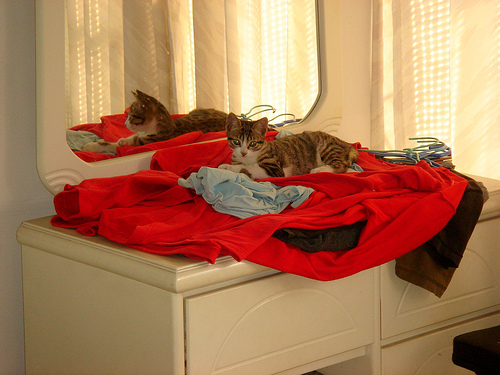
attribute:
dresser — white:
[14, 173, 498, 373]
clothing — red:
[46, 128, 489, 305]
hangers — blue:
[353, 134, 456, 169]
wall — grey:
[4, 65, 66, 183]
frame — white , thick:
[31, 0, 373, 195]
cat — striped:
[226, 107, 376, 173]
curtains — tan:
[386, 12, 497, 164]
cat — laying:
[211, 109, 369, 181]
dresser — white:
[6, 205, 496, 374]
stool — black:
[452, 322, 497, 373]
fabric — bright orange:
[50, 130, 466, 280]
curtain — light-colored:
[372, 0, 497, 182]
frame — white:
[16, 117, 96, 208]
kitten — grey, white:
[223, 110, 358, 180]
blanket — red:
[55, 141, 467, 279]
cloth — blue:
[176, 165, 312, 219]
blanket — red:
[49, 129, 467, 281]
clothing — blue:
[182, 167, 308, 220]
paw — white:
[223, 161, 277, 189]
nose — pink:
[239, 149, 249, 155]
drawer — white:
[173, 269, 387, 374]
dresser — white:
[17, 120, 498, 372]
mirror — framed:
[55, 1, 330, 169]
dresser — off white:
[15, 119, 491, 341]